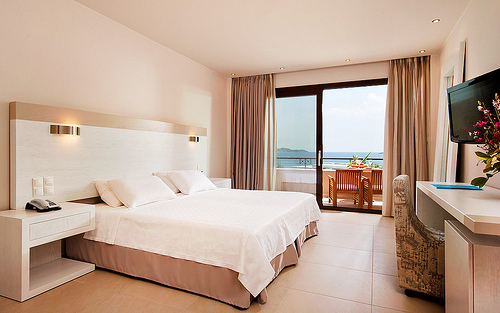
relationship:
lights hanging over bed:
[43, 112, 88, 144] [71, 173, 335, 311]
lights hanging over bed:
[176, 116, 213, 149] [71, 173, 335, 311]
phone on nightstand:
[26, 198, 63, 210] [0, 202, 100, 302]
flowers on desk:
[466, 89, 498, 183] [415, 180, 499, 311]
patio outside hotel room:
[273, 78, 387, 209] [1, 0, 499, 310]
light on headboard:
[187, 132, 199, 145] [9, 95, 216, 210]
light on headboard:
[47, 121, 82, 142] [9, 95, 216, 210]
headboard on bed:
[9, 95, 216, 210] [72, 174, 319, 306]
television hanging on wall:
[445, 67, 498, 145] [438, 0, 498, 194]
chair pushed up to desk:
[325, 142, 447, 308] [415, 180, 499, 311]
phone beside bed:
[23, 197, 61, 213] [108, 155, 302, 256]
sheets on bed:
[60, 220, 326, 310] [60, 165, 320, 309]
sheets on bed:
[82, 184, 322, 299] [60, 165, 320, 309]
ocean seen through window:
[279, 150, 383, 167] [274, 86, 384, 213]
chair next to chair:
[328, 166, 363, 208] [362, 168, 383, 208]